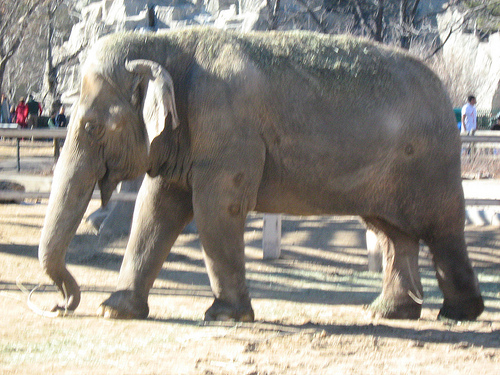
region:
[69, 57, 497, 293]
large elephant with small legs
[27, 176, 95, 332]
trunk of elephant touching ground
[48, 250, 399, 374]
dirt ground under elephant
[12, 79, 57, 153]
woman in red in distance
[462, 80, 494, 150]
man in white in distance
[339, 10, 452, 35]
trees in background behind elephant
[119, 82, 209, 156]
flappy ear on side of elephant's face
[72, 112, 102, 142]
small eye of elephant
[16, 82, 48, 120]
man in black in distance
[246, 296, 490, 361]
shadow of elephant being cast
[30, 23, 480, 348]
a grey elephant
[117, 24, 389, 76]
a green mat on the elephant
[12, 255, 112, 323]
his trunk picking up a a stick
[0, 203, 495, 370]
the grass is brown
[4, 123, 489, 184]
a fence behind the elephant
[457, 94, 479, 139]
a man behind the fence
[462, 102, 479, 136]
his shirt is white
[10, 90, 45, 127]
people behind the fence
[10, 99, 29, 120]
a red jacket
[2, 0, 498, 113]
a rocky cliff behind the people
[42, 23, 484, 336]
An old elephant walking through the dirt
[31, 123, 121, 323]
The elephant's trunk touches the ground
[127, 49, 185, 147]
A large ear on the elephant's head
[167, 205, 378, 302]
Black shadows on the ground beneath the elephant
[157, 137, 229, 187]
Wrinkled grey skin on the elephant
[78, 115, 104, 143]
The elephant's eye is closed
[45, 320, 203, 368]
Brown dirt covers the ground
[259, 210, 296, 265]
A white fence post behind the elephant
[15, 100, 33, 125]
A woman in red in the distance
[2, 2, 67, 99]
Dead brown trees behind the elephant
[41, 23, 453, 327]
this is an elephant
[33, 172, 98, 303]
this is the trunk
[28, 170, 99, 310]
the trunk is long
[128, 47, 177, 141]
this is the ear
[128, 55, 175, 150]
the ear is short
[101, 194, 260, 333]
these are the legs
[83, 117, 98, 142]
this is the eye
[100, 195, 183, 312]
the leg is in front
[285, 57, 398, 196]
this is the belly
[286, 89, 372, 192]
the belly is fat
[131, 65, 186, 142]
elephants ear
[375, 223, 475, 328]
the elephants back legs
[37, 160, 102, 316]
the elephants trunk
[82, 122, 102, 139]
the elephants eye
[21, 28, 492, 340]
the elephant is grey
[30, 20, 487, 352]
the elephant is standing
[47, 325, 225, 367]
the dirt on the ground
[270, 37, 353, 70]
hair on the elephant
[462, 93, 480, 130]
a person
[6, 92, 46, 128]
people walking